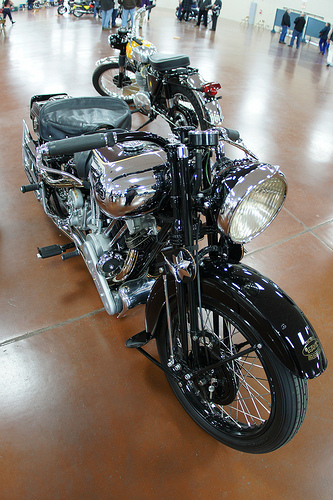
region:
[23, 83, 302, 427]
shiny bike on floor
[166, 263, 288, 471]
black wheel on bike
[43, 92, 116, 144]
grey seat on bike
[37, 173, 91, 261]
chrome pipes on bike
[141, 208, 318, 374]
black frame around tires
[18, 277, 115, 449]
floor is brown tile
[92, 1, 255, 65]
people are away from bike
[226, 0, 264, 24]
white wall behind people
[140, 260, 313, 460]
wheel of a bike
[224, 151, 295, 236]
light of a bike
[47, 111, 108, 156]
hand of a bike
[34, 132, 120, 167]
a handle of a bike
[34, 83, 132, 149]
seat of a bike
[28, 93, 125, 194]
back of a bike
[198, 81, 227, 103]
tail light of a bike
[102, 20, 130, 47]
handle of a bike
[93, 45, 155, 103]
wheel of a bike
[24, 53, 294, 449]
a motorcycle on display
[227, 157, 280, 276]
a large round headlight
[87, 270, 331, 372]
a black front fender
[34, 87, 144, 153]
a wide black seat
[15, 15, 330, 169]
reflection of light on the floor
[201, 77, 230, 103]
a red tail light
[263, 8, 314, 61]
two men standing together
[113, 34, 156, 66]
yellow gas tank on bike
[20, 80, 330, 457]
a gleaming motorcycle on display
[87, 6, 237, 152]
another motorcycle on display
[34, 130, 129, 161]
the motorcycle has gray handlebars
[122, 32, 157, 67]
this motorcycle has yellow detailing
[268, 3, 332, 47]
a couple of chalkboards in the background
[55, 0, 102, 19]
other motorcycles on display in the background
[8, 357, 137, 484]
the floor color is brown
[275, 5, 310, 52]
these two men are wearing blue pants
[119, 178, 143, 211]
photographer reflected in the shiny metal surface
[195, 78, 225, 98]
motorcycle tail light is red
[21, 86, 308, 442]
motorized bike on floor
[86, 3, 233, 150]
motorized bike on floor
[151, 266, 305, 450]
tire in front of bike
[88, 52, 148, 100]
tire in front of bike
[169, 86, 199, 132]
rear tire of bike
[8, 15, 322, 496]
floor bikes rest on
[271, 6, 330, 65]
people standing near boards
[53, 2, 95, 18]
bikes in the back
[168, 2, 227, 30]
people near a bike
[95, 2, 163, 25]
people near group of bikes